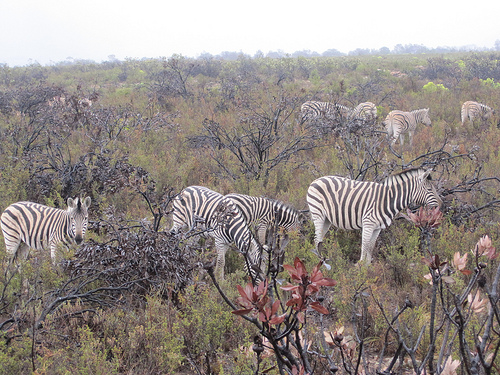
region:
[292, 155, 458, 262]
A black and white zebra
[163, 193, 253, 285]
A black and white zebra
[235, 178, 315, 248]
A black and white zebra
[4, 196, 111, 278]
A black and white zebra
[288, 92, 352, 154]
A black and white zebra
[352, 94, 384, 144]
A black and white zebra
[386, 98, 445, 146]
A black and white zebra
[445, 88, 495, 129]
A black and white zebra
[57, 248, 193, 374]
A short brown tree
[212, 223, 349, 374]
A short brown tree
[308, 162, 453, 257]
Black and white zebra in a field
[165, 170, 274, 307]
Black and white zebra in a field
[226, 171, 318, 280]
Black and white zebra in a field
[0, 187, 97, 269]
Black and white zebra in a field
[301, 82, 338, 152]
Black and white zebra in a field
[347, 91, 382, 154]
Black and white zebra in a field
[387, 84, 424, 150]
Black and white zebra in a field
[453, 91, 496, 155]
Black and white zebra in a field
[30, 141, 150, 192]
Large brush in a field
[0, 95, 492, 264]
group of zebras on the plain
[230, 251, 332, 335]
brown leaves on branch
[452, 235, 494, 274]
tan leaves on branch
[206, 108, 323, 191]
small tree with no leaves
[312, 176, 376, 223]
black and white stripes on back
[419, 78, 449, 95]
green leaves on tree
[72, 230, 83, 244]
black nose and mouth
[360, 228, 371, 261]
pale grey stripes on leg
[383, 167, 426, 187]
black and white striped mane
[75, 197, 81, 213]
black stripe on head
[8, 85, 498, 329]
zebras in the wild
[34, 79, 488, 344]
zebras in the wild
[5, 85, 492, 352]
zebras in the wild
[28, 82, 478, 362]
zebras in the wild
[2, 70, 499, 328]
zebras in the wild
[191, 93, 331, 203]
a bare gray tree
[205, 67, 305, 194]
a bare gray tree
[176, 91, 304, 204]
a bare gray tree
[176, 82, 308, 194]
a bare gray tree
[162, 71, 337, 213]
a bare gray tree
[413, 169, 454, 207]
head of a zebra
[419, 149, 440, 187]
ear of a zebra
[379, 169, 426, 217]
neck of a zebra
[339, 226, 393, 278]
leg of a zebra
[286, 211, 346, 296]
leg of a zebra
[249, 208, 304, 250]
neck of a zebra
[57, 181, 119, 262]
head of a zebra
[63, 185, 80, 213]
ear of a zebra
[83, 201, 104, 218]
ear of a zebra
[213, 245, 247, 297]
leg of a zebra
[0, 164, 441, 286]
the zebras have stripes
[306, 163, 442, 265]
the zebra is standing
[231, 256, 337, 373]
the leaves are brown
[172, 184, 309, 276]
two zebra grazing in the brush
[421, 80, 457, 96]
bright green leaves on far bush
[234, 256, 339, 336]
red leaves on black branches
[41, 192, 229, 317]
black leaves cling to black branch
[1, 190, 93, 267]
one zebra faces to it's right side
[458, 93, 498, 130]
rear of a zebra grazing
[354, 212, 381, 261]
zebra's stripes fade on the legs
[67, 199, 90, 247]
a face with a black nose